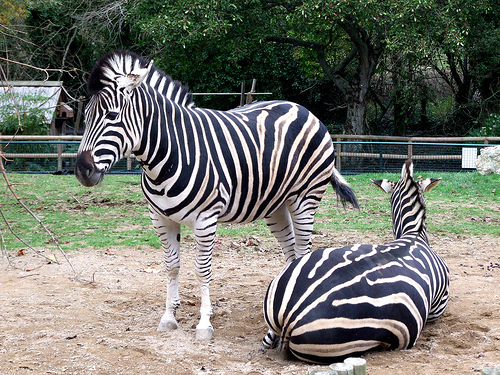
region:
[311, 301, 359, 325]
black stripe on zebra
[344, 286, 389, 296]
black stripe on zebra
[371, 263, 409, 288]
black stripe on zebra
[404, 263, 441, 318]
black stripe on zebra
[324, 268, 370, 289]
black stripe on zebra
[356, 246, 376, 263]
black stripe on zebra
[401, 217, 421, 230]
black stripe on zebra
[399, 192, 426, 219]
black stripe on zebra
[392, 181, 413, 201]
black stripe on zebra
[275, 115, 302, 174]
black stripe on zebra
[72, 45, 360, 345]
The zebra is standing.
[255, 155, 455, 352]
The zebra's face is not visible.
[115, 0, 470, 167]
The tree has green leaves.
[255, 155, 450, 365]
The zebra is sitting in dirt.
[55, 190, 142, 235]
Green grass is growing.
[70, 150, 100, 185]
The zebra has a black nose and mouth.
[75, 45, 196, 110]
The zebra has a white and black mane.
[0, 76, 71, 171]
The building in the background is behind a fence.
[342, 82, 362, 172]
The tree trunk is made of wood.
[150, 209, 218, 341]
The zebra has two front legs.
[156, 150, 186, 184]
black stripe on zebra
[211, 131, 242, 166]
black stripe on zebra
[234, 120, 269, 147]
black stripe on zebra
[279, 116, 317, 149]
black stripe on zebra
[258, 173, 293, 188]
black stripe on zebra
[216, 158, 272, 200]
black stripe on zebra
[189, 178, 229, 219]
black stripe on zebra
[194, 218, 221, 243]
black stripe on zebra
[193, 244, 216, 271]
black stripe on zebra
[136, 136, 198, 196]
black stripe on zebra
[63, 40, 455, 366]
two zebras in the dirt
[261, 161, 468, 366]
a zebra laying in the dirt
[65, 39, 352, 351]
a zebra standing in the dirt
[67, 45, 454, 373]
a zebra standing next to a zebra laying down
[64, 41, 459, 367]
a zebra laying down next to a zebra standing up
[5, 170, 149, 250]
grass on the ground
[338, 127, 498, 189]
a fence in the distance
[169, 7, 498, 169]
trees beyond the fence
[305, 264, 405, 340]
stripes on a zebra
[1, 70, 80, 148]
a shed beyond the fence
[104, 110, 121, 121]
eye of a zebra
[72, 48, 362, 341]
zebra standing on a dirt ground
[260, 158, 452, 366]
zebra sitting on a ground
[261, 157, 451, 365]
zebra laying down on a dirt ground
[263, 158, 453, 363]
the back of a zebra laying down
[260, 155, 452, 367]
zebra resting on a dirt ground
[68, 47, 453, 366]
zebra standing next to a resting zebra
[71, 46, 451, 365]
zebra laying down next to a standing zebra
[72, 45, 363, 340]
standing zebra looking straight ahead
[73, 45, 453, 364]
two zebras on a dirt ground